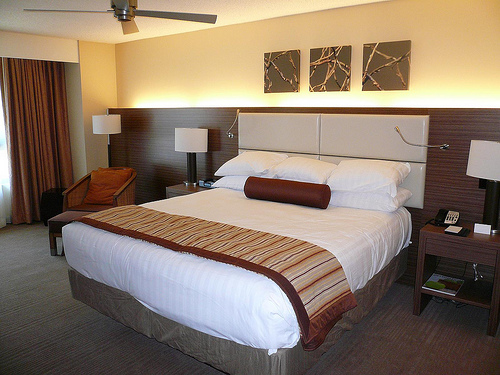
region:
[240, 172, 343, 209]
red pillow on bed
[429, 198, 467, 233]
telephone on night stand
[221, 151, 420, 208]
six white pillows on bed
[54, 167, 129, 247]
chair with foot rest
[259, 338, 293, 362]
corner of sheet no tucked in all the way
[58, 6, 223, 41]
fan on ceiling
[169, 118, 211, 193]
black and white lamp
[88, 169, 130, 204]
orange pillows in chair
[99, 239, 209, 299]
white sheet on bed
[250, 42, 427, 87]
camo art work on wall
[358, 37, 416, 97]
The picture is square.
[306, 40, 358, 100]
The picture is square.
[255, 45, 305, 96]
The picture is square.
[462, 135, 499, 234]
The lamp has a white shade.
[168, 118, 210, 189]
The lamp has a white shade.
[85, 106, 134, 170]
The lamp has a white shade.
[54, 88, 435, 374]
The bed is neatly made.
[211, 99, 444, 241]
The headboard is white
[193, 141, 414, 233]
The pillows have white pillow cases on them.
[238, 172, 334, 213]
The pillow is brown.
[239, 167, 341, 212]
A RED BEDROLL ON THE BED.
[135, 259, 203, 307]
THE SHEETS ARE WHITE.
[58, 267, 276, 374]
GRAY SKIRTING ON THE BOTTOM OF THE BED.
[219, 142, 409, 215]
THE BED HAS SIX PILLOWS.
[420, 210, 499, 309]
A SMALL BEDSIDE TABLE.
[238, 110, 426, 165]
A WHITE, TILED HEAD BOARD.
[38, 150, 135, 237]
A SMALL CHAIR BY THE BED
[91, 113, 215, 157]
SEVERAL LAMP SHADES IN THE ROOM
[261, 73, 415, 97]
THREE PAINTINGS ABOVE THE BED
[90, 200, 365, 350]
A MULTI COLORED BLANKET ON THE BED.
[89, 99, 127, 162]
One of three lamps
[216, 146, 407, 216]
Six pillows sitting on the bed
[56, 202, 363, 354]
Coverlet on top of the sheets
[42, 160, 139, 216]
Chair next to the bed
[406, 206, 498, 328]
Night stand next to the bed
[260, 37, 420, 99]
Three decorative pictures on the wall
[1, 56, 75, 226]
Brown colored window curtains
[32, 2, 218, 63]
Ceiling fan with four blades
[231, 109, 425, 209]
White headboard at head of the bed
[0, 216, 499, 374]
Carpet with lines through it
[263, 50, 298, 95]
painting above hotel bed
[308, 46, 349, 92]
painting above hotel bed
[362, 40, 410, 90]
painting above hotel bed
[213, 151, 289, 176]
white pillow on hotel bed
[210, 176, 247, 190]
white pillow on hotel bed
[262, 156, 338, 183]
white pillow on hotel bed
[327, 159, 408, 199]
white pillow on hotel bed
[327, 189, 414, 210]
white pillow on hotel bed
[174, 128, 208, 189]
lamp on wooden table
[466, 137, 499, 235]
lamp on wooden table